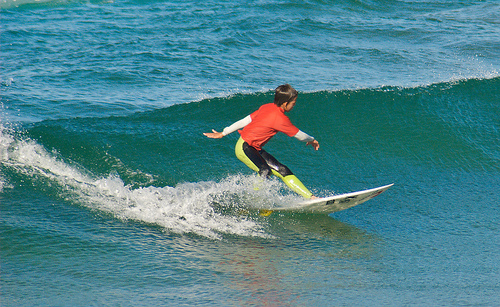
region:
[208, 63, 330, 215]
young boy on surfboard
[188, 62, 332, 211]
young boy wearing orange shirt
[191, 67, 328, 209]
young boy wearing black and yellow pants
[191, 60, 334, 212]
young boy with short brown hair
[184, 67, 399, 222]
boy riding on surfboard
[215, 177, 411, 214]
white surfboard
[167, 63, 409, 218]
young boy surfing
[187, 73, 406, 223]
boy turning on surfboard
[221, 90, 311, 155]
orange and white shirt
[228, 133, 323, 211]
black and neon yellow pants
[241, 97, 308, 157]
THE KID IS WEARING A RED SHIRT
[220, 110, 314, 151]
THE KID HAS WHITE SLEEVES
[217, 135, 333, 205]
THE KID IS WEARING BLACK AND YELLOW PANTS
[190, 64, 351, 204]
THE KID IS WET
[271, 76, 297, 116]
THE KID HAS SHORT HAIR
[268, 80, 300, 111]
THE KID HAS BROWN HAIR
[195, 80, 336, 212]
THE KID IS SURFING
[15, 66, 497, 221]
THE KID IS ON A WAVE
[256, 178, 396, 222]
THE SURFBOARD IS WHITE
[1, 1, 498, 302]
THE WATER IS BLUE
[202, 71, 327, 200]
the boy surfing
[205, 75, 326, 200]
the person surfing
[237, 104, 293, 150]
the rod shirt on the boy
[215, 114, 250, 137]
the white sleeves on the shirt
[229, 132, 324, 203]
the black and green pants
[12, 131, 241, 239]
the water in motion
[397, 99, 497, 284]
the blue and green ocean water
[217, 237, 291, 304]
the reflection in the water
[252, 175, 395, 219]
the white surfboard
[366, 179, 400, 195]
the point on the surf board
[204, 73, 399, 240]
a surfer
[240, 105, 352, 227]
a surfer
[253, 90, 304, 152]
a surfer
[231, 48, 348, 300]
a surfer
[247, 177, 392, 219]
A white surfboard in the water.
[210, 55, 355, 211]
A boy surfing in the water.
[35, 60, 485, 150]
A small surfable wave.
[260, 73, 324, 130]
Short brown hair on boy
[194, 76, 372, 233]
Black and green wet suit pants.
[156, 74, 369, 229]
A boy wearing a red and white shirt.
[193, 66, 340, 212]
A boy wearing two shirts.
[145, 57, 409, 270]
A child surfing in the water.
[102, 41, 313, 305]
Water splashing from surfboard.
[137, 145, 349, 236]
Surfboard breaking water.